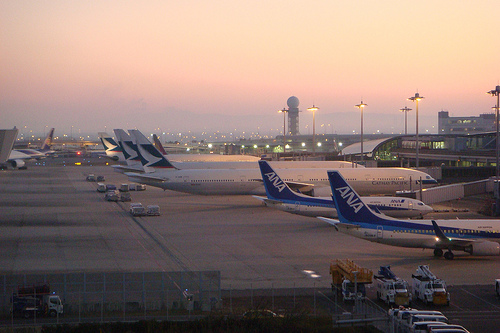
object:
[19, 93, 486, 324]
airport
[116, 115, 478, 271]
planes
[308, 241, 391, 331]
truck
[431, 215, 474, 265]
wings airplane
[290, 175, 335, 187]
windows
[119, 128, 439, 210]
airplane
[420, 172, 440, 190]
nose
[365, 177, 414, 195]
logo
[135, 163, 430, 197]
white airplane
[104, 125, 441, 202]
commercial airplane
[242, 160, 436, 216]
plane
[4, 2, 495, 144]
sky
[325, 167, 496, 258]
airplane